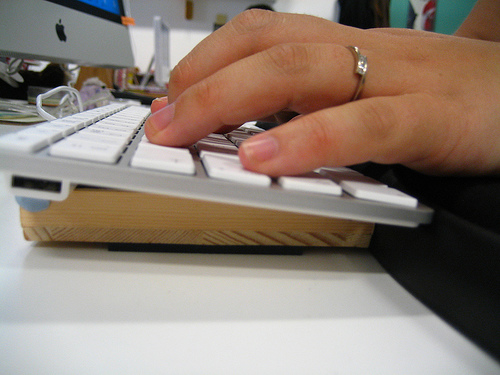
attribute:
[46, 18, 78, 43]
logo — black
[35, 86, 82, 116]
wire — white